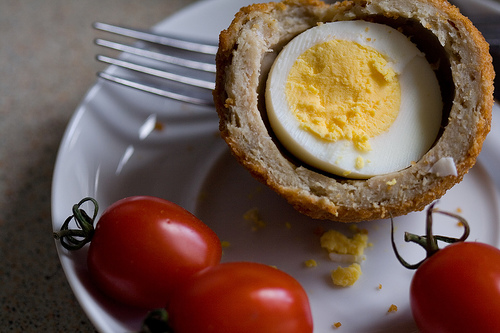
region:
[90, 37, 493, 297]
Food on the plate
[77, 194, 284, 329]
Red cherry tomatoes on plate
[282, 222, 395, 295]
Egg yolk crumbles on the plate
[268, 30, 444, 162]
Half of a hard boiled egg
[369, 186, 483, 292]
Stem on top of tomato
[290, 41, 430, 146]
Center of the egg is yellow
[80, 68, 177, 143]
Shadow on the plate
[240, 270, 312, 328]
Light shining on the tomato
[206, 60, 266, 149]
Bread surrounding the egg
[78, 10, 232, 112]
Fork on the plate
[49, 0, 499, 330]
petite breakfast on a white plate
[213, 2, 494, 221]
hard boiled egg surrounded by bread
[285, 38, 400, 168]
yellow hard boiled egg yolk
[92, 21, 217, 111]
silver tines of a metal fork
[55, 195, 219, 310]
shiny ripe red cherry tomato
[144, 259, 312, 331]
shiny ripe red cherry tomato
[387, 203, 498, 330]
shiny ripe red cherry tomato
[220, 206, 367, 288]
wayward crumbs of egg yolk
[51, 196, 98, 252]
green stem of tomato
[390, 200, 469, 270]
brownish green stem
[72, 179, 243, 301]
the tomatoes are red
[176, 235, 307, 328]
the tomatoes are red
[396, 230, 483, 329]
the tomatoes are red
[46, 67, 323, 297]
the plate is white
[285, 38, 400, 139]
hard boiled egg yolk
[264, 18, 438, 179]
hard boiled egg white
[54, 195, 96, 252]
green leafy stem on tomato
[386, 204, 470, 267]
green leafy stem on tomato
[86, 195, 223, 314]
tomato is on white plate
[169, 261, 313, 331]
tomato is on white plate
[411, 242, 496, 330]
tomato is on white plate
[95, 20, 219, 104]
fork laying on white plate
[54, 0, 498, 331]
white plate with tomato on it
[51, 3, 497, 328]
white plate with fork on it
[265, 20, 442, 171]
half of a cooked egg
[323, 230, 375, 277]
a yolk of an egg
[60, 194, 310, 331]
fresh ripe tomatos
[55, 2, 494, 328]
a plate of breakfast foods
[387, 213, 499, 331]
tomatos on the vine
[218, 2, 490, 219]
an egg inside of bread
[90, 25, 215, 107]
four prongs of a fork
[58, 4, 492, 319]
a plate full of food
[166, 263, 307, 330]
a juicy red tomato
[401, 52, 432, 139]
egg whites